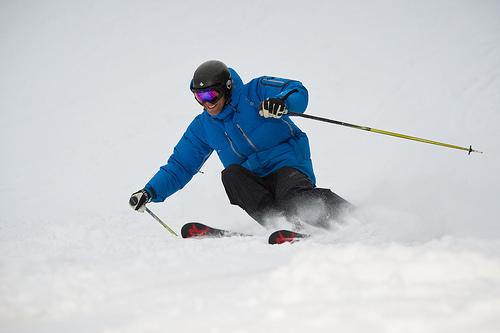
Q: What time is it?
A: Daytime.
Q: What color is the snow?
A: White.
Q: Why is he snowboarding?
A: For fun.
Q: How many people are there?
A: One.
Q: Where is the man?
A: On a ski slope.